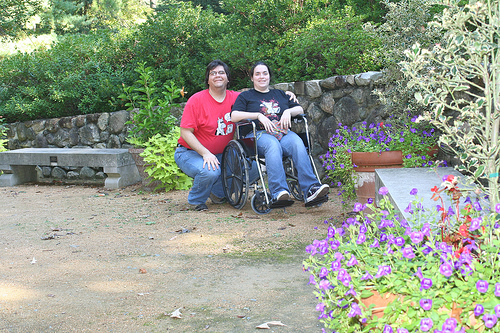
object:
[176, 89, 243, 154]
shirt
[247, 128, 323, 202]
jeans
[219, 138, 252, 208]
wheel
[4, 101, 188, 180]
wall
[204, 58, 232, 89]
hair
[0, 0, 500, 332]
backyard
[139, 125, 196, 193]
bush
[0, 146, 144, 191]
bench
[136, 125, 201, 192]
plant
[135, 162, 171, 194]
pot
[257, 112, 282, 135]
hand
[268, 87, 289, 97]
shouler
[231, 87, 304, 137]
shirt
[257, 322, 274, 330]
leaf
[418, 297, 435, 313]
flowers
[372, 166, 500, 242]
bench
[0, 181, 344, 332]
dirt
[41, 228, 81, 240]
gravel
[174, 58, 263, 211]
man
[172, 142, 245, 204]
blue jeans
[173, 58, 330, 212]
friends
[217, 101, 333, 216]
wheel chair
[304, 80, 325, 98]
stone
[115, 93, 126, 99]
leaves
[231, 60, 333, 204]
people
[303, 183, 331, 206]
shoe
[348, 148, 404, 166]
brick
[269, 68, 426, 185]
wall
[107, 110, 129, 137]
stone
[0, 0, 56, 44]
tree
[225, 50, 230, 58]
leaves